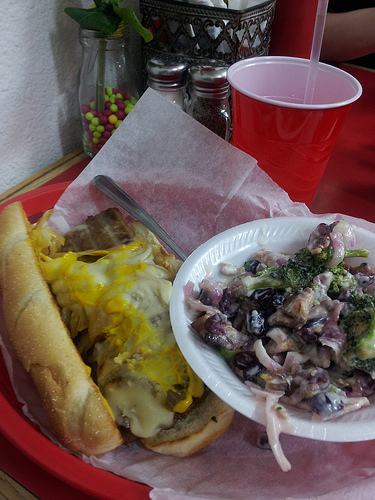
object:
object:
[81, 91, 131, 149]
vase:
[76, 29, 144, 163]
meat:
[47, 204, 210, 431]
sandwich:
[0, 197, 235, 462]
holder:
[142, 0, 280, 59]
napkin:
[195, 0, 262, 14]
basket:
[0, 134, 375, 498]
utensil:
[89, 173, 190, 261]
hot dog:
[2, 193, 219, 462]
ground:
[282, 108, 375, 220]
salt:
[147, 55, 188, 109]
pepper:
[187, 59, 230, 143]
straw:
[299, 0, 332, 107]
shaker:
[140, 56, 188, 119]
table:
[0, 79, 375, 500]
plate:
[0, 172, 375, 500]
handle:
[92, 172, 192, 267]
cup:
[219, 53, 361, 221]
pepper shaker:
[182, 54, 236, 145]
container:
[221, 55, 365, 215]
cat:
[180, 225, 375, 426]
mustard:
[68, 257, 147, 358]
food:
[0, 197, 375, 454]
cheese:
[79, 240, 170, 431]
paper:
[35, 89, 375, 500]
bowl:
[168, 208, 375, 448]